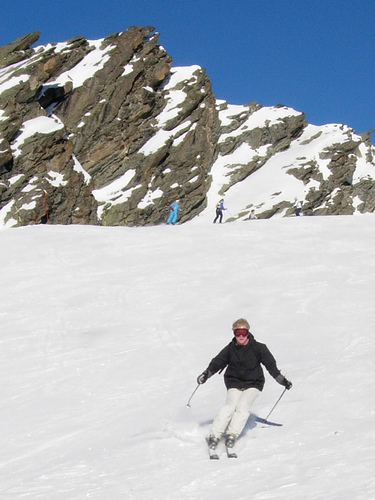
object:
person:
[166, 199, 184, 225]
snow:
[0, 204, 373, 499]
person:
[214, 199, 228, 223]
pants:
[214, 208, 224, 222]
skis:
[203, 431, 240, 462]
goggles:
[234, 328, 248, 336]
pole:
[187, 384, 201, 405]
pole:
[263, 383, 289, 424]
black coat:
[204, 333, 285, 391]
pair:
[211, 387, 260, 438]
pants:
[210, 388, 259, 438]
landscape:
[0, 25, 374, 500]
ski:
[224, 439, 236, 458]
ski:
[204, 436, 217, 461]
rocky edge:
[8, 37, 237, 217]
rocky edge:
[252, 100, 373, 209]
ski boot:
[225, 432, 234, 448]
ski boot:
[207, 432, 218, 451]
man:
[197, 318, 294, 451]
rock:
[1, 24, 221, 226]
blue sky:
[166, 0, 374, 147]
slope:
[0, 222, 363, 500]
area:
[0, 213, 374, 498]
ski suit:
[166, 200, 179, 223]